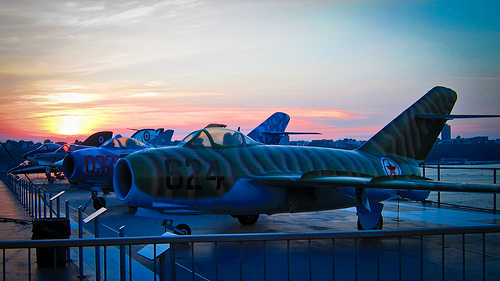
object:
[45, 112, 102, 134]
sun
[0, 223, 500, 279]
fence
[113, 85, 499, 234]
airplane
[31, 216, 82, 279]
garbage can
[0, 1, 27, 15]
clouds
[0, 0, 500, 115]
sky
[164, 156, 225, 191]
number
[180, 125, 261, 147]
cockpit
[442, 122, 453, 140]
building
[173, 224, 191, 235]
front wheel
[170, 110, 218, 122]
clouds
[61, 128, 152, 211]
airplane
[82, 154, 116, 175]
number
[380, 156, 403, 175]
emblem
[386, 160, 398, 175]
star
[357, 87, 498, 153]
tail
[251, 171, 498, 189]
wing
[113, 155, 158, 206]
nose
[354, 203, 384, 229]
rear landing gear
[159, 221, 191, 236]
front landing gear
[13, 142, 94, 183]
airplane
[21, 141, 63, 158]
airplane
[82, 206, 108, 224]
sign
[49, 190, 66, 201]
sign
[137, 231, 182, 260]
sign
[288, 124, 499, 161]
city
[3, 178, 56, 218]
railing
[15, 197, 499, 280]
concrete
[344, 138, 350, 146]
trees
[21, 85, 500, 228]
airplanes